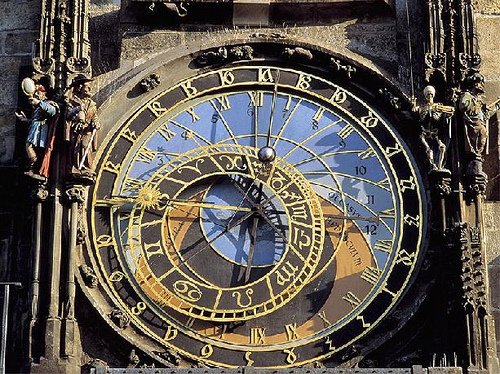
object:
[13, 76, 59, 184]
sculpture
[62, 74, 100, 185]
sculpture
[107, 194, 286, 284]
hands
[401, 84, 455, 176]
statue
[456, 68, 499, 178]
statue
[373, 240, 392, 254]
numeral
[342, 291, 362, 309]
xi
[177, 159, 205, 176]
aries sign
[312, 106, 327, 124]
roman numeral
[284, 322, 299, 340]
numeral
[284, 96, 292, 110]
number i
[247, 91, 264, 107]
numbers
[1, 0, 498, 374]
wall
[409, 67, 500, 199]
skeleton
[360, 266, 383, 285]
numeral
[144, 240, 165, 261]
gemini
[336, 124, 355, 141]
number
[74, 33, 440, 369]
astrological clock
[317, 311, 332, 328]
x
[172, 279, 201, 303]
sign